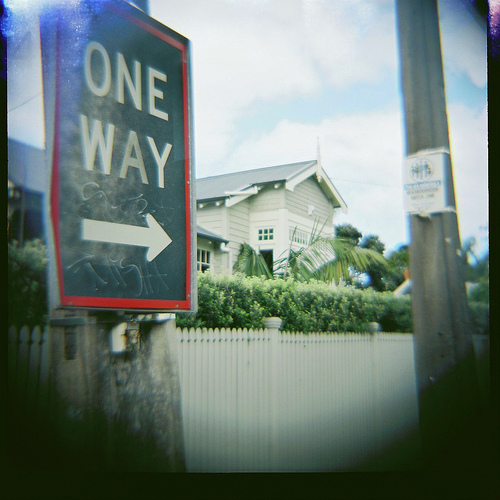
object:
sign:
[36, 1, 197, 314]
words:
[81, 41, 172, 189]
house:
[6, 137, 349, 276]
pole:
[393, 0, 478, 470]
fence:
[1, 325, 491, 473]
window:
[196, 247, 210, 272]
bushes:
[9, 215, 491, 327]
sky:
[1, 1, 497, 266]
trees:
[338, 223, 388, 309]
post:
[41, 0, 197, 473]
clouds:
[197, 0, 489, 223]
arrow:
[82, 213, 173, 262]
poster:
[403, 148, 451, 215]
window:
[259, 228, 274, 240]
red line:
[179, 48, 190, 308]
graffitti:
[63, 179, 169, 298]